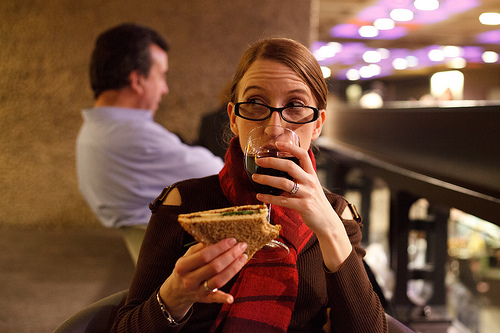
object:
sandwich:
[178, 204, 282, 265]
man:
[75, 21, 224, 228]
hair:
[88, 22, 169, 97]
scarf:
[211, 134, 317, 332]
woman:
[115, 37, 385, 331]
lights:
[358, 26, 380, 38]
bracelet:
[156, 291, 181, 326]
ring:
[290, 182, 299, 194]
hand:
[251, 141, 334, 232]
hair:
[231, 38, 326, 108]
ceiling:
[317, 0, 499, 81]